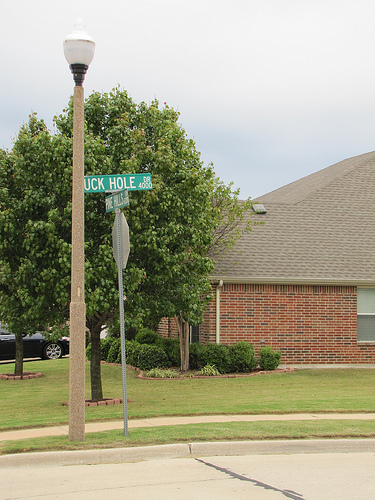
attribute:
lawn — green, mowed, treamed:
[1, 354, 374, 453]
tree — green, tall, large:
[1, 81, 267, 404]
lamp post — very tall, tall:
[63, 14, 97, 444]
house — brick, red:
[153, 150, 375, 368]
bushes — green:
[85, 325, 280, 372]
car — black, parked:
[1, 325, 70, 359]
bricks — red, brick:
[2, 370, 42, 380]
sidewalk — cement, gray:
[1, 410, 374, 441]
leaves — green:
[1, 83, 267, 332]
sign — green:
[85, 173, 153, 191]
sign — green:
[104, 190, 131, 211]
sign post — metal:
[115, 208, 131, 439]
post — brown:
[68, 84, 88, 444]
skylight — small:
[253, 202, 267, 215]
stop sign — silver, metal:
[112, 211, 131, 268]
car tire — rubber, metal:
[44, 341, 64, 359]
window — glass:
[357, 287, 375, 343]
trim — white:
[356, 287, 374, 342]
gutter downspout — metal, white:
[215, 280, 225, 344]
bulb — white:
[63, 12, 98, 65]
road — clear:
[1, 449, 375, 498]